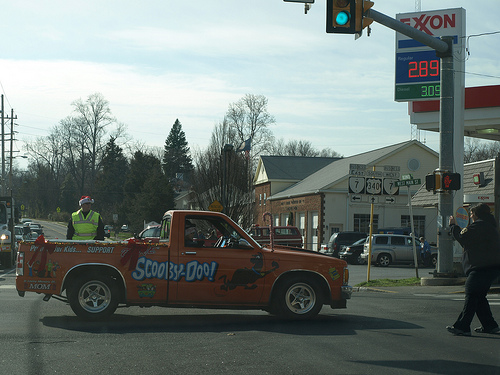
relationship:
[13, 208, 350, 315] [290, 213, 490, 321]
truck sitting lot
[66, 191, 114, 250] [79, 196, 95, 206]
man wearing hat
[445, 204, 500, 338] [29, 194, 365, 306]
person taking truck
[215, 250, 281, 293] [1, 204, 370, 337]
scooby doo painted on truck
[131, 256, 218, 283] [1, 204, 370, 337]
letter painted on truck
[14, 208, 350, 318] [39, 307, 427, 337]
truck casting shadow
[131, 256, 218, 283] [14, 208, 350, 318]
letter painted on truck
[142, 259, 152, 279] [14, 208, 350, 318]
letter painted on truck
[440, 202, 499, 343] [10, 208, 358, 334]
person photographing truck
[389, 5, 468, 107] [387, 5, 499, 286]
sign advertising gas station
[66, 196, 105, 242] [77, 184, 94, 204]
man wearing hat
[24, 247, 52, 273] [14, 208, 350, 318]
bow attached to truck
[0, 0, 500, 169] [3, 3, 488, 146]
cloud hanging in sky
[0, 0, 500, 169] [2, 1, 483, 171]
cloud hanging in sky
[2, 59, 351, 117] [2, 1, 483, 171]
cloud hanging in sky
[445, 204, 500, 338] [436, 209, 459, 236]
person holding camera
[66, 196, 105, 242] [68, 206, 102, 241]
man wearing safety vest